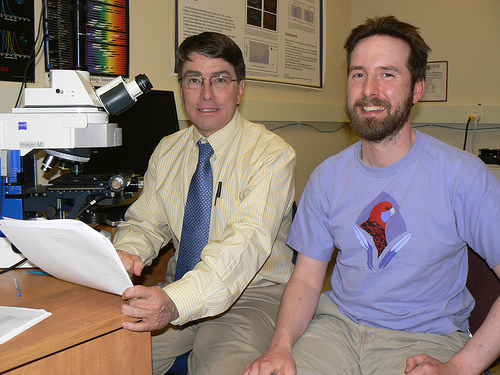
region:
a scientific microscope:
[5, 65, 151, 227]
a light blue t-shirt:
[288, 129, 498, 329]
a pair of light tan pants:
[295, 287, 480, 374]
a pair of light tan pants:
[150, 283, 285, 374]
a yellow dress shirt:
[113, 112, 297, 325]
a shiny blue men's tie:
[173, 142, 215, 287]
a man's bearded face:
[340, 16, 430, 145]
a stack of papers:
[0, 219, 132, 296]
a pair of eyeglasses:
[176, 73, 238, 89]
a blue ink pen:
[7, 273, 24, 299]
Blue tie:
[172, 140, 214, 284]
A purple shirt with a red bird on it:
[284, 127, 497, 337]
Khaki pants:
[149, 277, 291, 373]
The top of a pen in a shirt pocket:
[212, 179, 223, 205]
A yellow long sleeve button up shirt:
[111, 106, 296, 327]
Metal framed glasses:
[176, 72, 246, 89]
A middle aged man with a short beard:
[240, 12, 497, 372]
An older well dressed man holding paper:
[0, 30, 297, 372]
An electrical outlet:
[469, 105, 484, 125]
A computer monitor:
[91, 85, 180, 177]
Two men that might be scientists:
[147, 25, 457, 273]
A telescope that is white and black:
[23, 59, 158, 220]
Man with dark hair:
[335, 18, 431, 155]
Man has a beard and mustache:
[336, 14, 434, 152]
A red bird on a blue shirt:
[291, 152, 490, 285]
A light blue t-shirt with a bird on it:
[310, 139, 475, 327]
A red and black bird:
[351, 181, 418, 276]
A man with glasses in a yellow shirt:
[153, 39, 281, 234]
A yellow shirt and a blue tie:
[148, 119, 260, 258]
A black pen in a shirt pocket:
[207, 176, 233, 224]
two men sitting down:
[86, 20, 486, 366]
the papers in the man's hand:
[0, 213, 140, 303]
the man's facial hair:
[342, 95, 412, 139]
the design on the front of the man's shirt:
[348, 188, 410, 273]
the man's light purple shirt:
[283, 134, 499, 331]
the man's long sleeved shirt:
[115, 118, 296, 330]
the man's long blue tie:
[173, 138, 213, 283]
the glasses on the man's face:
[178, 71, 237, 89]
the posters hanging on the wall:
[4, 3, 335, 93]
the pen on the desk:
[13, 276, 24, 297]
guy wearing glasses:
[105, 30, 282, 346]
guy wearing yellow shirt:
[113, 18, 284, 315]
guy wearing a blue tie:
[116, 24, 298, 344]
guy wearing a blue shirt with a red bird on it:
[288, 8, 498, 364]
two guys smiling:
[103, 12, 498, 371]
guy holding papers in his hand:
[0, 21, 280, 363]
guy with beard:
[287, 10, 498, 372]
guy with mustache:
[258, 3, 498, 373]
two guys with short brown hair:
[113, 2, 492, 372]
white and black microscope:
[0, 51, 153, 246]